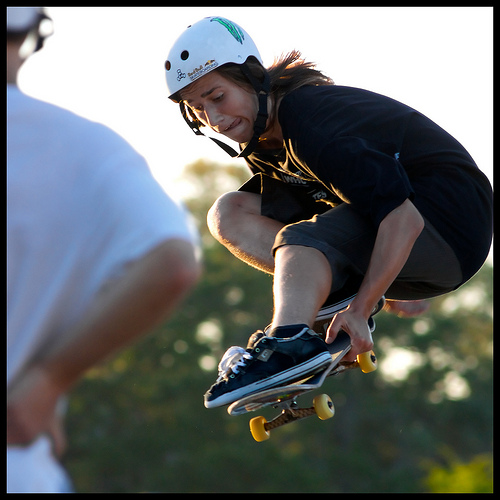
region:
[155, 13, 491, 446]
Young man skateboarding.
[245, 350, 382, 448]
Yellow wheels on the skateboard.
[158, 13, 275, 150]
White helmet on the head.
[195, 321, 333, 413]
Black shoe on the foot.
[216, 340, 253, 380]
White shoelaces on the shoe.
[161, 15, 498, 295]
Young man wearing a black shirt.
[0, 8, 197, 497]
Person in a white shirt.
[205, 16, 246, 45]
Green design on the helmet.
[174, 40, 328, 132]
Brown hair on the young man.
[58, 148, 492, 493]
Trees in the background.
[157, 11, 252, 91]
white skateboarding helmet on head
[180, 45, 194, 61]
black hole on front of helmet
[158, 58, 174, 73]
black hole on front of helmet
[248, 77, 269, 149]
black chin strap from helmet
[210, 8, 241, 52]
green logo on side of helmet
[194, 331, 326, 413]
black skate shoes on feet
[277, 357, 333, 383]
white bottom of shoes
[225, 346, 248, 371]
white laces from skate shoes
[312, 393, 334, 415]
yellow wheels on skateboard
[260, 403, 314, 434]
trucks from skate board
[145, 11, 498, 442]
skater in the air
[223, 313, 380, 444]
a skateboard is color black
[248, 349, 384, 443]
wheels of skateboard are yellow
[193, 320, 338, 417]
a black shoe with white sole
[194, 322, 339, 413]
a black shoe with white pins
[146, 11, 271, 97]
a white helmet with green design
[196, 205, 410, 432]
a hand holding a skateboard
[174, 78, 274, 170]
strap of a helmet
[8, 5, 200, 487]
a person wearing a white shirt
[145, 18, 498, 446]
man wears a black top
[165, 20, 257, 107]
white skate boarding helmet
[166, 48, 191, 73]
two holes on front of helmet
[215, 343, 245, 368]
white skate shoe laces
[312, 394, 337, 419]
yellow wheels on trucks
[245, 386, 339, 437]
skate board wheels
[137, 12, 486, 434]
man riding skate board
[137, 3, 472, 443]
man in the air with board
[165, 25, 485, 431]
A teenager is on a skateboard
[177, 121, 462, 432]
The skateboarder is in the air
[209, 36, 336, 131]
The teenager has long hair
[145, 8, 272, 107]
The person is wearing a white helmet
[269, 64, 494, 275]
The person is wearing a black shirt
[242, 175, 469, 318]
The person is wearing dark shorts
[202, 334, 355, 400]
The person is wearing black shoes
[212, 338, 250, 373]
The shoelaces are white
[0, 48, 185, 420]
The person is wearing a white shirt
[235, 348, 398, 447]
The wheels of the skateboard are yellow